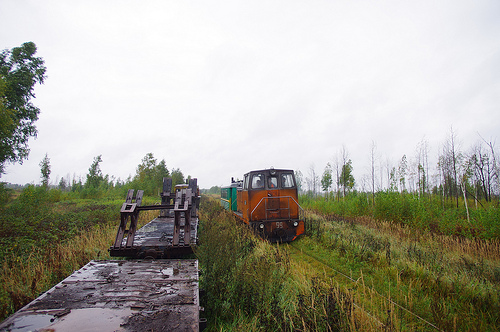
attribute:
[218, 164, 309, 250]
train — orange, green, moving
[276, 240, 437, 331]
tracks — grass-covered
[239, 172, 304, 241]
train engine — orange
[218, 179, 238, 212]
train cars — green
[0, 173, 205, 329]
flatbed rail car — old, gray, brown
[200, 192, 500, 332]
grass — green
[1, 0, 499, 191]
sky — cloudy, overcast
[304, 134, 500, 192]
trees — bare, small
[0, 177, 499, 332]
field — grassy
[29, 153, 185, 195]
trees — green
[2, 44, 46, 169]
leaves — green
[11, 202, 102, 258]
weeds — tall